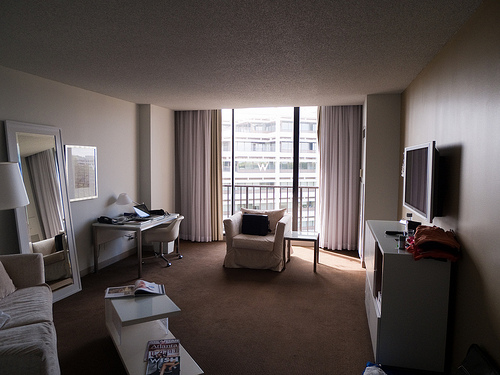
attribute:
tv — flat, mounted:
[403, 141, 435, 224]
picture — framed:
[64, 146, 100, 201]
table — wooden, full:
[280, 231, 320, 272]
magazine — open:
[105, 280, 167, 298]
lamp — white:
[1, 162, 30, 213]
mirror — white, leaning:
[6, 121, 83, 297]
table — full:
[92, 215, 176, 280]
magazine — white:
[146, 341, 178, 375]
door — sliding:
[227, 106, 318, 208]